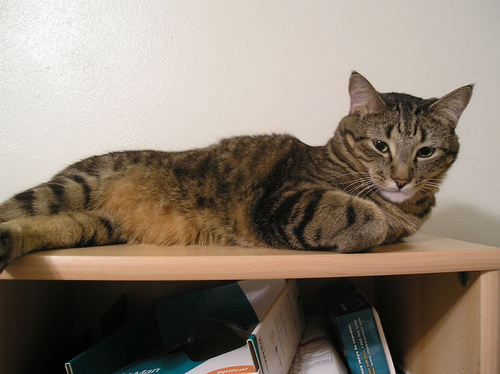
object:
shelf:
[0, 233, 499, 373]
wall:
[2, 0, 498, 244]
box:
[323, 280, 396, 373]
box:
[66, 280, 303, 373]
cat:
[0, 70, 475, 272]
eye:
[370, 138, 389, 154]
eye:
[416, 145, 435, 158]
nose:
[393, 177, 409, 191]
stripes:
[395, 97, 404, 138]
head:
[348, 71, 474, 203]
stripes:
[52, 181, 69, 211]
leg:
[267, 187, 387, 252]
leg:
[2, 175, 101, 218]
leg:
[0, 211, 114, 274]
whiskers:
[340, 173, 394, 200]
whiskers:
[415, 178, 475, 206]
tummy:
[114, 183, 198, 247]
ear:
[348, 70, 387, 116]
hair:
[356, 83, 367, 108]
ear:
[428, 83, 473, 129]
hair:
[442, 102, 457, 116]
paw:
[0, 227, 12, 274]